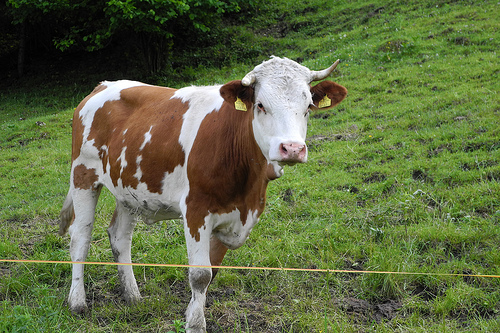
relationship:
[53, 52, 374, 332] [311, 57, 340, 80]
cow has horns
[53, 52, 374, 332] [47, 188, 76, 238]
cow has tail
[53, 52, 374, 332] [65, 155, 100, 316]
cow has legs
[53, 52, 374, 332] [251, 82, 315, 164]
cow has face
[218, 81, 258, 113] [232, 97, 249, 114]
ear has tag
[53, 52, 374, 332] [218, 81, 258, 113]
cow has ear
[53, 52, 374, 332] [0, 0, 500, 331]
cow walks on hill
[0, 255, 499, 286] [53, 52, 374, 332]
string contains cow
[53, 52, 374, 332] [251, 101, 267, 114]
cow has eyes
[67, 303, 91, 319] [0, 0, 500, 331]
foot in hill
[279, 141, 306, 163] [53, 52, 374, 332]
nose on cow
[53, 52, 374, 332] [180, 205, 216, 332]
cow has front leg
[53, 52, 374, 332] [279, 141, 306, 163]
cow has nose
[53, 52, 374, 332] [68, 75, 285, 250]
cow has body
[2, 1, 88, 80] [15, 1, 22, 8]
tree has leaf